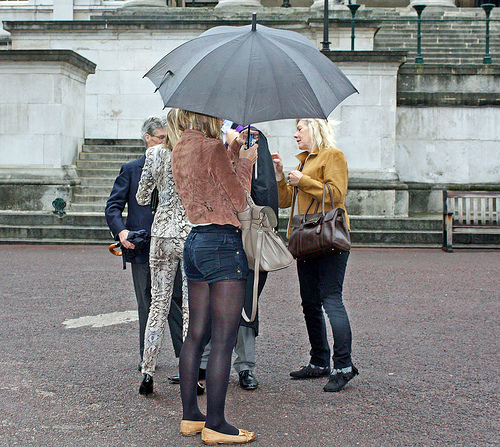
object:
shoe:
[201, 424, 253, 445]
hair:
[173, 110, 187, 129]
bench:
[443, 187, 499, 252]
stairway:
[0, 137, 499, 248]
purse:
[287, 182, 350, 259]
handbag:
[236, 188, 294, 322]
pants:
[297, 249, 351, 375]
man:
[104, 117, 183, 371]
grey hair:
[144, 118, 160, 130]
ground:
[1, 241, 498, 446]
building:
[1, 1, 500, 245]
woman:
[271, 119, 359, 394]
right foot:
[287, 365, 332, 379]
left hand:
[288, 170, 304, 187]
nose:
[294, 131, 299, 138]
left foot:
[323, 367, 357, 392]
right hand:
[271, 153, 284, 180]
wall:
[0, 49, 98, 184]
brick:
[33, 104, 67, 135]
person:
[171, 106, 257, 445]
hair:
[315, 118, 331, 150]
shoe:
[323, 366, 359, 393]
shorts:
[183, 226, 248, 285]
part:
[73, 133, 119, 245]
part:
[144, 13, 359, 128]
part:
[23, 318, 79, 428]